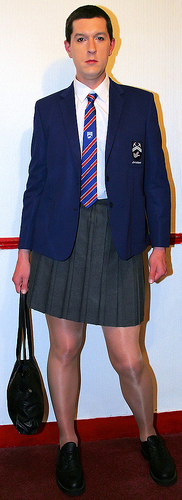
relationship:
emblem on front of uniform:
[130, 141, 143, 164] [16, 74, 171, 328]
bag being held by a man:
[6, 290, 44, 436] [10, 1, 179, 500]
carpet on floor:
[0, 438, 182, 499] [5, 415, 170, 490]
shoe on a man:
[136, 428, 175, 484] [10, 1, 179, 500]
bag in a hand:
[6, 290, 44, 436] [11, 259, 31, 293]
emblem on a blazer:
[131, 141, 143, 165] [14, 77, 172, 256]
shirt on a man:
[73, 76, 109, 205] [10, 1, 179, 500]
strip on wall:
[2, 232, 176, 250] [3, 4, 173, 419]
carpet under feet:
[0, 438, 182, 499] [54, 422, 173, 492]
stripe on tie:
[88, 93, 93, 99] [78, 93, 101, 207]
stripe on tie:
[84, 115, 96, 129] [78, 93, 101, 207]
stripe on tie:
[81, 160, 96, 179] [78, 93, 101, 207]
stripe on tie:
[78, 148, 95, 166] [78, 93, 101, 207]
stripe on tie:
[81, 182, 95, 197] [76, 92, 98, 206]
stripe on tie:
[82, 138, 95, 155] [79, 94, 98, 207]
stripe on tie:
[84, 192, 98, 204] [78, 93, 101, 207]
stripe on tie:
[85, 101, 90, 107] [78, 93, 101, 207]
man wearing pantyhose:
[10, 1, 179, 500] [44, 326, 88, 443]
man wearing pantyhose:
[10, 1, 179, 500] [102, 325, 154, 437]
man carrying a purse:
[10, 1, 179, 500] [5, 272, 46, 434]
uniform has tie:
[16, 74, 171, 328] [78, 93, 101, 207]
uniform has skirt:
[18, 43, 153, 338] [48, 194, 152, 326]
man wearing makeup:
[10, 1, 179, 500] [72, 31, 111, 70]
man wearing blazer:
[10, 1, 179, 500] [20, 78, 168, 244]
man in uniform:
[10, 1, 179, 500] [16, 74, 171, 328]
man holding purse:
[10, 1, 179, 500] [5, 272, 46, 434]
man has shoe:
[58, 1, 121, 120] [43, 430, 181, 499]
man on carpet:
[10, 1, 179, 500] [24, 430, 167, 468]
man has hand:
[10, 1, 179, 500] [149, 243, 172, 297]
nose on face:
[82, 39, 104, 59] [70, 13, 128, 70]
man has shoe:
[10, 1, 179, 500] [50, 431, 173, 498]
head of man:
[62, 10, 124, 83] [10, 1, 179, 500]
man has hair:
[10, 1, 179, 500] [55, 4, 131, 39]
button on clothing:
[100, 195, 125, 220] [17, 76, 172, 264]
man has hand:
[10, 1, 179, 500] [136, 233, 168, 289]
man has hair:
[10, 1, 179, 500] [61, 0, 115, 45]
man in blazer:
[10, 1, 179, 500] [20, 67, 173, 258]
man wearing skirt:
[10, 1, 179, 500] [8, 192, 155, 335]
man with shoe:
[10, 1, 179, 500] [139, 430, 177, 486]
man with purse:
[10, 1, 179, 500] [7, 280, 46, 438]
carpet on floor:
[99, 443, 131, 477] [97, 472, 139, 498]